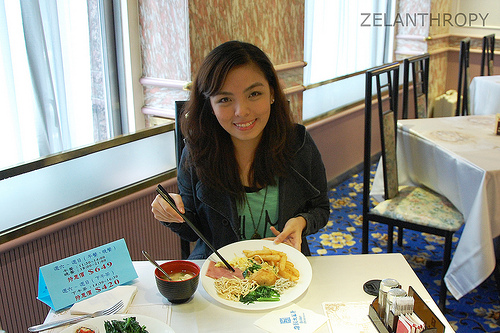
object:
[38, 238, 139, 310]
sign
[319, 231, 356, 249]
flower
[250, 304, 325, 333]
napkin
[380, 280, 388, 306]
spice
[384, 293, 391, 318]
spice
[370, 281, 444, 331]
tray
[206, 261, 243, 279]
food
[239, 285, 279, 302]
food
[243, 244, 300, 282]
food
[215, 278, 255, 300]
food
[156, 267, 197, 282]
soup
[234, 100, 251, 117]
nose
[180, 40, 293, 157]
hair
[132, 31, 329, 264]
woman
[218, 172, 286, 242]
shirt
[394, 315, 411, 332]
packets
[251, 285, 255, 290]
noodles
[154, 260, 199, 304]
bowl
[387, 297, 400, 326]
spices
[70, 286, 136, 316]
towel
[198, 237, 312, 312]
plate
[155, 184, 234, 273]
chopsticks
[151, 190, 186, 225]
hand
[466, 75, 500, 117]
table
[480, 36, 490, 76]
chair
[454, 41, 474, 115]
chair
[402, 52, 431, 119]
chair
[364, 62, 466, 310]
chair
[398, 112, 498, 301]
tablecloth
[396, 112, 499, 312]
table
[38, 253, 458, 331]
table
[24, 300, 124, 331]
fork